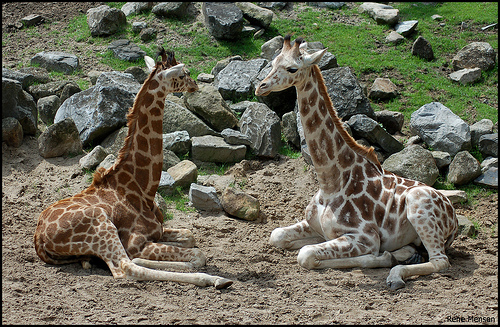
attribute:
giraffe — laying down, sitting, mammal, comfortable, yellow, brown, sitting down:
[35, 47, 233, 290]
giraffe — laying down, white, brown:
[255, 37, 459, 290]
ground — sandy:
[3, 158, 500, 325]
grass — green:
[284, 14, 462, 74]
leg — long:
[40, 212, 233, 288]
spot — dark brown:
[136, 133, 149, 151]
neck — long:
[110, 90, 166, 203]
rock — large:
[54, 73, 143, 149]